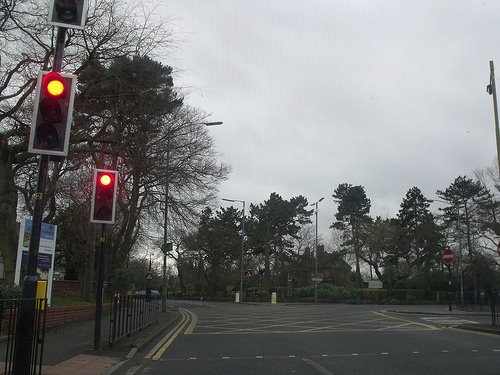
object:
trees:
[241, 189, 311, 287]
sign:
[429, 233, 465, 278]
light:
[92, 168, 116, 223]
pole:
[94, 220, 109, 350]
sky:
[0, 11, 500, 279]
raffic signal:
[24, 66, 81, 158]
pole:
[222, 197, 247, 302]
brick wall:
[0, 303, 114, 338]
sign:
[440, 249, 459, 263]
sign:
[15, 216, 58, 308]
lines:
[181, 299, 441, 333]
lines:
[186, 311, 444, 336]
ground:
[40, 294, 498, 375]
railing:
[108, 295, 165, 345]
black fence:
[0, 292, 174, 375]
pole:
[9, 156, 56, 375]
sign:
[28, 69, 78, 160]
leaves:
[236, 214, 357, 304]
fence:
[107, 289, 163, 346]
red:
[48, 77, 66, 96]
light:
[28, 73, 76, 156]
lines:
[146, 309, 208, 360]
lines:
[199, 315, 416, 331]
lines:
[300, 354, 334, 374]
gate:
[36, 287, 103, 371]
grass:
[48, 291, 107, 307]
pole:
[160, 101, 170, 311]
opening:
[128, 300, 134, 341]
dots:
[159, 358, 164, 362]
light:
[177, 120, 223, 131]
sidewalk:
[20, 296, 167, 375]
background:
[0, 0, 500, 298]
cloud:
[327, 52, 410, 102]